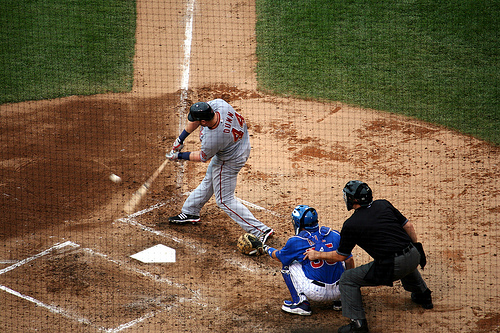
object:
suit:
[331, 201, 441, 331]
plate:
[129, 243, 177, 266]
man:
[123, 99, 275, 257]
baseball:
[105, 173, 122, 183]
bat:
[122, 142, 177, 214]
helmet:
[187, 102, 214, 124]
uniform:
[182, 99, 276, 245]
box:
[3, 242, 204, 333]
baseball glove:
[235, 233, 265, 259]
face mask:
[341, 182, 374, 211]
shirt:
[331, 196, 433, 281]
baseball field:
[2, 4, 499, 331]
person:
[300, 184, 440, 332]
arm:
[300, 247, 352, 265]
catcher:
[260, 201, 356, 318]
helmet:
[287, 202, 323, 230]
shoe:
[170, 211, 199, 225]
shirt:
[272, 232, 353, 282]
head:
[189, 104, 226, 134]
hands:
[161, 137, 182, 159]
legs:
[171, 159, 275, 246]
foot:
[170, 208, 206, 229]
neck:
[208, 108, 221, 130]